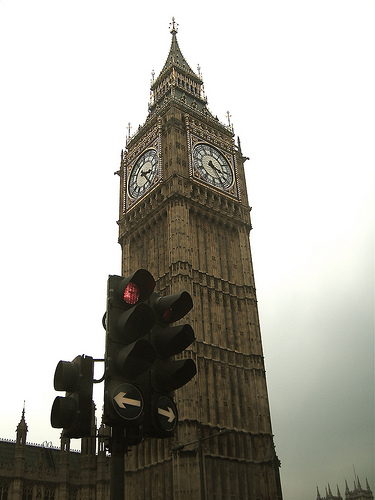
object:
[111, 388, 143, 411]
arrow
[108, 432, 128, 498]
pole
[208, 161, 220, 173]
hands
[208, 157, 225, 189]
hands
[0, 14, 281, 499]
building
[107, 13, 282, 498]
clock tower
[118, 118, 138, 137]
cross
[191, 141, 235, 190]
clock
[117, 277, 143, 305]
red light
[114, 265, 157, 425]
traffic light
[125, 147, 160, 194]
clock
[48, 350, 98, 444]
traffic light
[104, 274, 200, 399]
light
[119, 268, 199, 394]
signal light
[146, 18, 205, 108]
steeple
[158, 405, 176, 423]
arrow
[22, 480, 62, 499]
windows